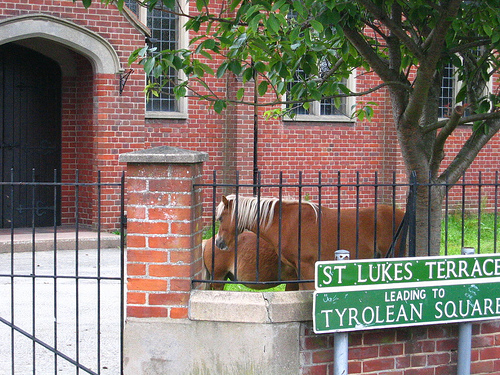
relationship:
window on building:
[145, 0, 186, 117] [0, 1, 498, 231]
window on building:
[145, 0, 186, 117] [0, 13, 123, 248]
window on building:
[286, 12, 312, 113] [0, 13, 123, 248]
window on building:
[440, 57, 455, 118] [0, 13, 123, 248]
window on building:
[145, 0, 186, 117] [0, 2, 498, 186]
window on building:
[440, 57, 455, 118] [0, 2, 498, 186]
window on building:
[322, 41, 344, 113] [0, 2, 498, 186]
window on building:
[286, 12, 312, 113] [0, 2, 498, 186]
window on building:
[440, 57, 455, 118] [0, 1, 498, 231]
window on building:
[286, 12, 312, 113] [0, 1, 498, 231]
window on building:
[440, 57, 455, 118] [2, 1, 493, 259]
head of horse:
[217, 192, 238, 249] [212, 191, 415, 288]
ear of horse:
[221, 192, 233, 209] [212, 191, 415, 288]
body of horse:
[282, 209, 424, 265] [200, 182, 454, 364]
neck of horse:
[235, 199, 304, 257] [212, 191, 415, 288]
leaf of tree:
[213, 99, 227, 114] [127, 0, 494, 260]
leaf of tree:
[234, 85, 247, 99] [127, 0, 494, 260]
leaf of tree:
[257, 78, 269, 97] [127, 0, 494, 260]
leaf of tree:
[216, 60, 230, 80] [127, 0, 494, 260]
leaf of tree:
[229, 59, 241, 76] [127, 0, 494, 260]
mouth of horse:
[212, 234, 232, 252] [219, 192, 409, 293]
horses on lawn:
[200, 190, 414, 292] [192, 209, 495, 293]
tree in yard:
[252, 2, 499, 260] [194, 205, 495, 293]